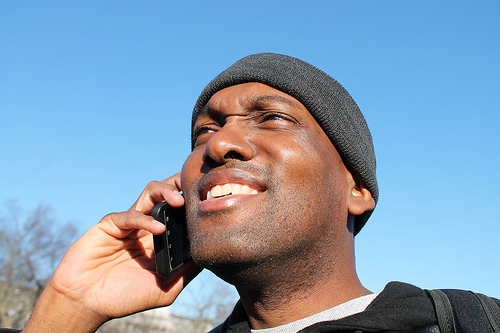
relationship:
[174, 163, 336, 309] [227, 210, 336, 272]
small hairs on jaw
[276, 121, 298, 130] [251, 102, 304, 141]
wrinkle around eye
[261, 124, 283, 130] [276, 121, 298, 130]
wrinkle around wrinkle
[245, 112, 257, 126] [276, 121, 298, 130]
wrinkle around wrinkle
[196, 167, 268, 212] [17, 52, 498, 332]
lips of a man